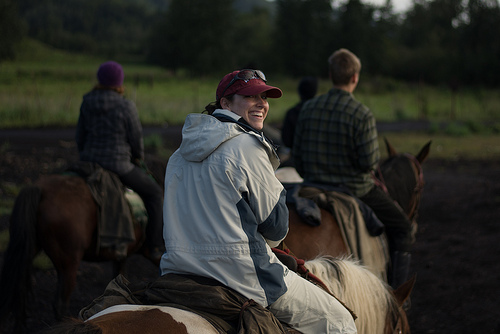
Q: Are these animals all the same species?
A: Yes, all the animals are horses.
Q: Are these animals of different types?
A: No, all the animals are horses.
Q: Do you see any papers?
A: No, there are no papers.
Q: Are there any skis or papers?
A: No, there are no papers or skis.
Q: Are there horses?
A: Yes, there is a horse.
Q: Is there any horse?
A: Yes, there is a horse.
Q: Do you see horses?
A: Yes, there is a horse.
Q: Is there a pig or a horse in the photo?
A: Yes, there is a horse.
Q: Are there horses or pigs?
A: Yes, there is a horse.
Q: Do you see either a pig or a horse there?
A: Yes, there is a horse.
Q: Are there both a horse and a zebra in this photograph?
A: No, there is a horse but no zebras.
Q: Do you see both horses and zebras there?
A: No, there is a horse but no zebras.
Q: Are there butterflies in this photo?
A: No, there are no butterflies.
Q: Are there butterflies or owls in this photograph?
A: No, there are no butterflies or owls.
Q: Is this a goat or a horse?
A: This is a horse.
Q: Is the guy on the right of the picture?
A: Yes, the guy is on the right of the image.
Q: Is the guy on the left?
A: No, the guy is on the right of the image.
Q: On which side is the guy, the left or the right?
A: The guy is on the right of the image.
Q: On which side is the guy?
A: The guy is on the right of the image.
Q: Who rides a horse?
A: The guy rides a horse.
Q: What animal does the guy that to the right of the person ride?
A: The guy rides a horse.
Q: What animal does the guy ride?
A: The guy rides a horse.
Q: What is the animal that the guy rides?
A: The animal is a horse.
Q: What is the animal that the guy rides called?
A: The animal is a horse.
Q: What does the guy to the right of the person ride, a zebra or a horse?
A: The guy rides a horse.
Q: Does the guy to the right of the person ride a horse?
A: Yes, the guy rides a horse.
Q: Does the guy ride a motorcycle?
A: No, the guy rides a horse.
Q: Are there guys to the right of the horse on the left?
A: Yes, there is a guy to the right of the horse.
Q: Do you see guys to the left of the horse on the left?
A: No, the guy is to the right of the horse.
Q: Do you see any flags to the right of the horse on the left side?
A: No, there is a guy to the right of the horse.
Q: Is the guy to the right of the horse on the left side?
A: Yes, the guy is to the right of the horse.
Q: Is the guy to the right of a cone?
A: No, the guy is to the right of the horse.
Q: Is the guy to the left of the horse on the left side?
A: No, the guy is to the right of the horse.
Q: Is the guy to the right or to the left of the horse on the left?
A: The guy is to the right of the horse.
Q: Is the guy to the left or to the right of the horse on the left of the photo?
A: The guy is to the right of the horse.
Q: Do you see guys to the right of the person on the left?
A: Yes, there is a guy to the right of the person.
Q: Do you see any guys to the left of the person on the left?
A: No, the guy is to the right of the person.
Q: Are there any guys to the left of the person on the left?
A: No, the guy is to the right of the person.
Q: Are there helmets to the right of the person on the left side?
A: No, there is a guy to the right of the person.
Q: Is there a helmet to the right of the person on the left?
A: No, there is a guy to the right of the person.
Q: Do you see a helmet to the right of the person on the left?
A: No, there is a guy to the right of the person.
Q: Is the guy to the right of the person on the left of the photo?
A: Yes, the guy is to the right of the person.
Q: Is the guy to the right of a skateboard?
A: No, the guy is to the right of the person.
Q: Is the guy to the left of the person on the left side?
A: No, the guy is to the right of the person.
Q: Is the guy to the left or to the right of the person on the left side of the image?
A: The guy is to the right of the person.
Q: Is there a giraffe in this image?
A: No, there are no giraffes.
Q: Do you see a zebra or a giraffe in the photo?
A: No, there are no giraffes or zebras.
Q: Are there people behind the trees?
A: Yes, there are people behind the trees.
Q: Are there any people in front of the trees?
A: No, the people are behind the trees.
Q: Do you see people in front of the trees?
A: No, the people are behind the trees.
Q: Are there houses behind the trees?
A: No, there are people behind the trees.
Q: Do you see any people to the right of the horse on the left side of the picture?
A: Yes, there are people to the right of the horse.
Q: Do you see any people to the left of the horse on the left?
A: No, the people are to the right of the horse.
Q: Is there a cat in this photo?
A: No, there are no cats.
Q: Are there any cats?
A: No, there are no cats.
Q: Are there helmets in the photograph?
A: No, there are no helmets.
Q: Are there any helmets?
A: No, there are no helmets.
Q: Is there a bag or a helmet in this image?
A: No, there are no helmets or bags.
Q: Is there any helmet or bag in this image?
A: No, there are no helmets or bags.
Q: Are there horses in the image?
A: Yes, there is a horse.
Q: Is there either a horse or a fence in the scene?
A: Yes, there is a horse.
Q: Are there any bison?
A: No, there are no bison.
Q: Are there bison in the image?
A: No, there are no bison.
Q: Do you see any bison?
A: No, there are no bison.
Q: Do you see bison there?
A: No, there are no bison.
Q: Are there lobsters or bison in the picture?
A: No, there are no bison or lobsters.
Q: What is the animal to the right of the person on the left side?
A: The animal is a horse.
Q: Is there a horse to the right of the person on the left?
A: Yes, there is a horse to the right of the person.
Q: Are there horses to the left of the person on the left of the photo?
A: No, the horse is to the right of the person.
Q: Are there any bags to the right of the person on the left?
A: No, there is a horse to the right of the person.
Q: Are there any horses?
A: Yes, there is a horse.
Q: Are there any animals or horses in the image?
A: Yes, there is a horse.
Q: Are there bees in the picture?
A: No, there are no bees.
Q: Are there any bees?
A: No, there are no bees.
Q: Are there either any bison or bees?
A: No, there are no bees or bison.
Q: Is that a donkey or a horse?
A: That is a horse.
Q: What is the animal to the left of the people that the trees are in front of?
A: The animal is a horse.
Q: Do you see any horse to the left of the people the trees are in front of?
A: Yes, there is a horse to the left of the people.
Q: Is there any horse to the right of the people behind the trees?
A: No, the horse is to the left of the people.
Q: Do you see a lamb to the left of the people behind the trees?
A: No, there is a horse to the left of the people.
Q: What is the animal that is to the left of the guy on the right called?
A: The animal is a horse.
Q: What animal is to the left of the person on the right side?
A: The animal is a horse.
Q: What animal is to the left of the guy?
A: The animal is a horse.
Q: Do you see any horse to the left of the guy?
A: Yes, there is a horse to the left of the guy.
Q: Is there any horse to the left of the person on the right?
A: Yes, there is a horse to the left of the guy.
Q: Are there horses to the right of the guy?
A: No, the horse is to the left of the guy.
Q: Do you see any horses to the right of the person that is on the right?
A: No, the horse is to the left of the guy.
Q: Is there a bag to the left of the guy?
A: No, there is a horse to the left of the guy.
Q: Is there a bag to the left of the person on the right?
A: No, there is a horse to the left of the guy.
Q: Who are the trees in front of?
A: The trees are in front of the people.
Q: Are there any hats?
A: Yes, there is a hat.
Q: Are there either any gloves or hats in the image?
A: Yes, there is a hat.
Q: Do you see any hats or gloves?
A: Yes, there is a hat.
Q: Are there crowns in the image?
A: No, there are no crowns.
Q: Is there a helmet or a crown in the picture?
A: No, there are no crowns or helmets.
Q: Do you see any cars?
A: No, there are no cars.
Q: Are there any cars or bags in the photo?
A: No, there are no cars or bags.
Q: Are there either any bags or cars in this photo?
A: No, there are no cars or bags.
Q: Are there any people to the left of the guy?
A: Yes, there is a person to the left of the guy.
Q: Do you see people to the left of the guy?
A: Yes, there is a person to the left of the guy.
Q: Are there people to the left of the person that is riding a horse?
A: Yes, there is a person to the left of the guy.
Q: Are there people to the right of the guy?
A: No, the person is to the left of the guy.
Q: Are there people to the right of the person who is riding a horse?
A: No, the person is to the left of the guy.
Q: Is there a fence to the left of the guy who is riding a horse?
A: No, there is a person to the left of the guy.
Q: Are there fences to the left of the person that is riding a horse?
A: No, there is a person to the left of the guy.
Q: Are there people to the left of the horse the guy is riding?
A: Yes, there is a person to the left of the horse.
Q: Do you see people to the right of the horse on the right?
A: No, the person is to the left of the horse.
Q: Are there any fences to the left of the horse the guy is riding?
A: No, there is a person to the left of the horse.